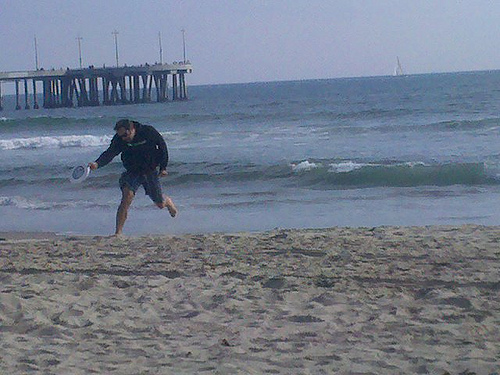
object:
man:
[88, 117, 178, 239]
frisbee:
[70, 162, 91, 183]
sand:
[0, 226, 499, 365]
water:
[0, 68, 499, 237]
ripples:
[287, 159, 360, 173]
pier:
[0, 28, 192, 111]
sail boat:
[392, 55, 404, 75]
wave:
[2, 130, 181, 152]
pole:
[34, 36, 39, 72]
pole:
[77, 37, 81, 70]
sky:
[2, 3, 496, 95]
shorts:
[118, 167, 165, 202]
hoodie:
[96, 121, 170, 173]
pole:
[181, 28, 189, 64]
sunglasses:
[117, 132, 134, 137]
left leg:
[143, 171, 179, 220]